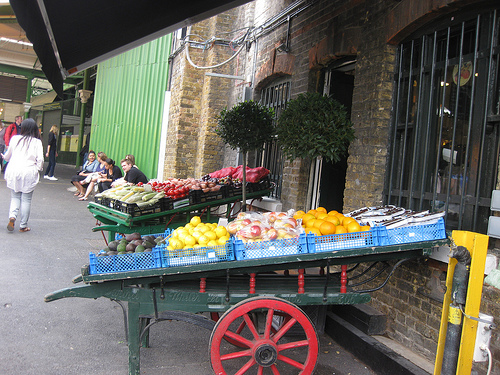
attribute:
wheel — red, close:
[219, 290, 319, 368]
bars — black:
[397, 43, 482, 162]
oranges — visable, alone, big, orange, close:
[309, 210, 363, 239]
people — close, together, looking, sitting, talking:
[86, 142, 155, 186]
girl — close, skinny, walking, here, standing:
[4, 111, 58, 246]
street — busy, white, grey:
[16, 235, 99, 367]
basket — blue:
[86, 224, 169, 274]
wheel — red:
[204, 293, 318, 373]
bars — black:
[379, 2, 499, 234]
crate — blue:
[304, 226, 371, 255]